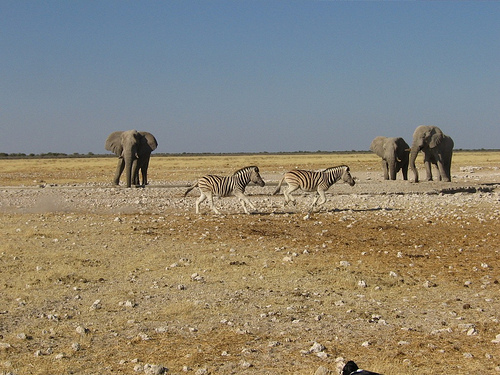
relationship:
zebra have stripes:
[180, 166, 266, 219] [209, 167, 337, 202]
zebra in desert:
[180, 166, 266, 219] [3, 152, 499, 373]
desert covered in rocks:
[3, 152, 499, 373] [76, 175, 499, 351]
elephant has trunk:
[104, 126, 153, 189] [121, 145, 136, 189]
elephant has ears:
[104, 126, 153, 189] [105, 130, 157, 159]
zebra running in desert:
[273, 159, 353, 211] [3, 152, 499, 373]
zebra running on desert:
[180, 166, 266, 219] [3, 152, 499, 373]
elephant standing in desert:
[104, 126, 153, 189] [3, 152, 499, 373]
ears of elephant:
[105, 130, 157, 159] [104, 126, 153, 189]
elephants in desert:
[374, 124, 448, 183] [3, 152, 499, 373]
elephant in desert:
[104, 126, 153, 189] [3, 152, 499, 373]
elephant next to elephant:
[375, 134, 406, 178] [409, 126, 450, 175]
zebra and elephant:
[180, 166, 266, 219] [104, 128, 158, 189]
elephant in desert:
[104, 128, 158, 189] [3, 152, 499, 373]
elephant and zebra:
[104, 128, 158, 189] [180, 166, 266, 219]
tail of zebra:
[179, 185, 193, 205] [189, 161, 263, 219]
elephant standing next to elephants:
[104, 126, 153, 189] [374, 124, 448, 183]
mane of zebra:
[234, 163, 254, 172] [189, 161, 263, 219]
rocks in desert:
[76, 175, 499, 351] [3, 152, 499, 373]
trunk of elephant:
[121, 145, 136, 189] [104, 126, 153, 189]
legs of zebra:
[274, 191, 299, 206] [273, 159, 353, 211]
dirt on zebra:
[288, 171, 307, 190] [273, 159, 353, 211]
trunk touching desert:
[125, 154, 133, 185] [3, 152, 499, 373]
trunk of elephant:
[125, 154, 133, 185] [104, 126, 153, 189]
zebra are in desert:
[180, 166, 266, 219] [3, 152, 499, 373]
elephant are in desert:
[104, 128, 158, 189] [3, 152, 499, 373]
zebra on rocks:
[180, 166, 266, 219] [76, 175, 499, 351]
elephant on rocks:
[104, 128, 158, 189] [76, 175, 499, 351]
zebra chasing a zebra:
[189, 161, 263, 219] [273, 159, 353, 211]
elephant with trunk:
[104, 126, 153, 189] [121, 145, 136, 189]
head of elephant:
[120, 134, 136, 163] [104, 126, 153, 189]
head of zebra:
[336, 164, 360, 192] [273, 159, 353, 211]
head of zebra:
[245, 162, 267, 190] [189, 161, 263, 219]